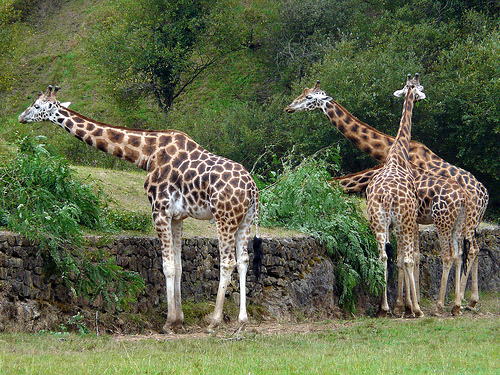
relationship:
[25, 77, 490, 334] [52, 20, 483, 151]
giraffes standing by trees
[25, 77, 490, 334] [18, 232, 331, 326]
giraffes standing by wall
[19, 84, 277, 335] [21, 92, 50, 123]
giraffe has head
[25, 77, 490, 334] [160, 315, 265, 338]
giraffes has hooves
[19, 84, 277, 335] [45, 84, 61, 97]
giraffe has horn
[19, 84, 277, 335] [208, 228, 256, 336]
giraffe has legs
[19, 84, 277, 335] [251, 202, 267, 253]
giraffe has tail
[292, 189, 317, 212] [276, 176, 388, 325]
leaves on bushes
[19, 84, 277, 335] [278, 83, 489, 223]
giraffe near another giraffe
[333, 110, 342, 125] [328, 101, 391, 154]
spot on neck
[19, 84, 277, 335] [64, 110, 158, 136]
giraffe has mane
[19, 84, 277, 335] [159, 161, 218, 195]
giraffe has spots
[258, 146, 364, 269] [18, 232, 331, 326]
bush over wall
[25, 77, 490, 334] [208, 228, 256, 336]
giraffes has legs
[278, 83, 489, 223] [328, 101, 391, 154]
giraffe has neck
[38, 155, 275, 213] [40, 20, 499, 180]
grass on hill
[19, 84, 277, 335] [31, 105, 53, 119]
giraffe has face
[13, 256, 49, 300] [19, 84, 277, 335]
stones in front of giraffe